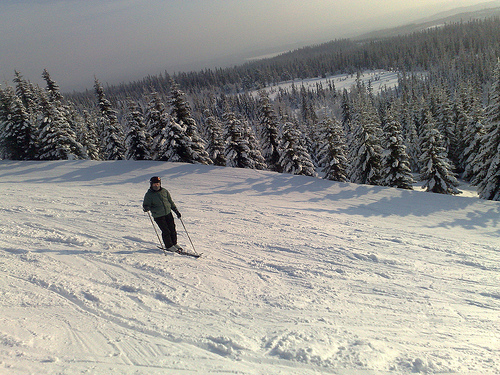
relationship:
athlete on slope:
[142, 176, 183, 252] [5, 152, 499, 374]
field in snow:
[0, 160, 500, 375] [2, 160, 495, 374]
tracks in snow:
[0, 190, 498, 373] [243, 283, 453, 335]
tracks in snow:
[0, 190, 498, 373] [181, 263, 442, 308]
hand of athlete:
[171, 210, 185, 219] [142, 176, 183, 252]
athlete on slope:
[142, 176, 183, 252] [125, 246, 436, 334]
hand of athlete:
[137, 199, 151, 211] [142, 176, 183, 252]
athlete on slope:
[142, 176, 183, 252] [116, 245, 346, 290]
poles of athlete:
[179, 217, 197, 254] [123, 177, 239, 267]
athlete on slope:
[123, 177, 239, 267] [5, 152, 499, 374]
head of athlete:
[126, 159, 176, 195] [142, 176, 183, 252]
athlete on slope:
[142, 176, 183, 252] [141, 240, 398, 330]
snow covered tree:
[306, 143, 347, 166] [315, 114, 353, 179]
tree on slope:
[315, 114, 353, 179] [293, 214, 417, 304]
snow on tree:
[177, 136, 489, 199] [419, 102, 461, 197]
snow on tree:
[177, 136, 489, 199] [384, 104, 419, 187]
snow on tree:
[177, 136, 489, 199] [350, 101, 390, 187]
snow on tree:
[177, 136, 489, 199] [316, 109, 350, 181]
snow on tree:
[177, 136, 489, 199] [271, 108, 320, 177]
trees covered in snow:
[56, 86, 478, 168] [300, 192, 391, 280]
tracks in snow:
[0, 190, 498, 373] [2, 160, 495, 374]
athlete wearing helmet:
[142, 176, 183, 252] [139, 173, 169, 186]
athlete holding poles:
[142, 176, 183, 252] [140, 207, 206, 256]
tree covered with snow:
[380, 111, 415, 191] [169, 77, 498, 201]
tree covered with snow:
[416, 92, 461, 193] [169, 77, 498, 201]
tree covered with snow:
[275, 101, 317, 177] [169, 77, 498, 201]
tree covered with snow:
[158, 107, 198, 162] [169, 77, 498, 201]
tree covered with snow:
[315, 114, 353, 179] [169, 77, 498, 201]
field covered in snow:
[0, 160, 500, 375] [1, 57, 495, 372]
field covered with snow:
[5, 160, 498, 372] [2, 160, 495, 374]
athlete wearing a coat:
[142, 176, 183, 252] [135, 189, 185, 221]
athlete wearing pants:
[142, 176, 183, 252] [158, 215, 179, 245]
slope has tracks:
[0, 180, 500, 372] [0, 190, 498, 373]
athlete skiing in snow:
[142, 176, 183, 252] [230, 233, 377, 345]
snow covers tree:
[2, 22, 499, 194] [215, 95, 255, 166]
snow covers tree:
[2, 22, 499, 194] [247, 77, 288, 171]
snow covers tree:
[2, 22, 499, 194] [312, 109, 356, 181]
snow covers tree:
[2, 22, 499, 194] [350, 101, 390, 187]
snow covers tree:
[2, 22, 499, 194] [37, 69, 92, 154]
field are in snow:
[0, 160, 500, 375] [2, 160, 495, 374]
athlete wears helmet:
[142, 176, 183, 252] [144, 175, 160, 183]